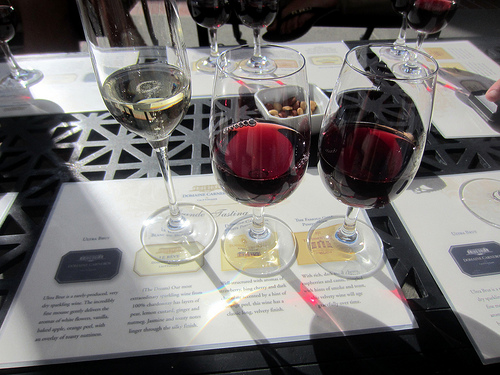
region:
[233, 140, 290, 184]
a glass with red wine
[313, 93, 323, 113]
a plate with nuts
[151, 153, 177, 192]
the neck of a glass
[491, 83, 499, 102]
the finger of a person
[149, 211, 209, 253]
the wine glass base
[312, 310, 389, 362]
the shadow of a wine glass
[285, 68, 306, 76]
the rim of a glass wine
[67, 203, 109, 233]
a mat supporting the glasses of wine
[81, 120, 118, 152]
a base holding the glasses of wine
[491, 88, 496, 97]
the finger nail of a person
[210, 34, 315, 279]
glass of red wine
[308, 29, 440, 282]
glass of red wine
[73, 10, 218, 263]
glass of white wine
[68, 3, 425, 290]
three glasses of wine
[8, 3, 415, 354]
three glasses of wine on a menu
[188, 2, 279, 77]
two glasses of wine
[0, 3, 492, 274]
several glasses of wine on table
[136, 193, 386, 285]
glass stems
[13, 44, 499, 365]
menus on table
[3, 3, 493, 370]
glasses of wine on table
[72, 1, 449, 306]
The wine glasses are on top of the menu.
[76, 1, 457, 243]
The glass of white wine is the first glass.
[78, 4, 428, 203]
The red wine glasses are next to the white wine.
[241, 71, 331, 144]
The bowl of nuts are on top of the table.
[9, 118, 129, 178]
The table is made of metal.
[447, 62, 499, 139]
The finger is touching the machine.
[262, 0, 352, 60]
The lady is wearing a black sandal.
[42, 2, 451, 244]
Only one glass of white wine is on the table.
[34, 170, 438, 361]
The menu is on top of the table.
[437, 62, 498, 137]
The machine is on top of the menu.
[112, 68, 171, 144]
Clear liquid in wine glass.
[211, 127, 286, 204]
Red wine in glass.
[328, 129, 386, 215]
Red wine in glass.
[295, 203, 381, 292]
Glass sitting on table.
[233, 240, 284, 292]
Glass sitting on table.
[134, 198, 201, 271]
Glass sitting on table.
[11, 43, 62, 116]
Wine glass across table.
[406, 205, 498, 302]
White paper on table.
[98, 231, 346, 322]
White paper on table.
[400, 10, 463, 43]
Red wine in glass on table.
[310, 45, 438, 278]
wine glass on table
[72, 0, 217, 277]
tall wine glass on table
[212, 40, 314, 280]
clear wine glass on table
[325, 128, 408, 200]
red wine inside of glass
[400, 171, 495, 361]
the restaurant's menu on the table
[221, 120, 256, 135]
bubbles in the wine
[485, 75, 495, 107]
a person's figertip at table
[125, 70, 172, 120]
white wine in the glass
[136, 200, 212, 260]
base of the wine glass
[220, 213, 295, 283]
base of the middle wine glass